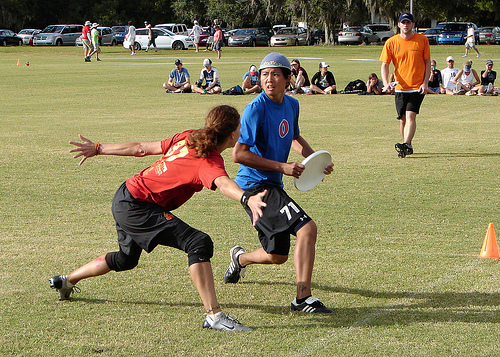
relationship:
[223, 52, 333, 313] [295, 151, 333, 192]
man playing with frisbee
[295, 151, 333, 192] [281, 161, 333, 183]
frisbee in hands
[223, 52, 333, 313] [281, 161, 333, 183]
man has hands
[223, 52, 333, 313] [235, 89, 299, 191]
man wearing a shirt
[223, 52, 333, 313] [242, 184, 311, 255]
man wearing shorts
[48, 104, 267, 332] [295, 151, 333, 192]
woman trying to block frisbee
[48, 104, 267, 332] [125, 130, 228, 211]
woman wearing a shirt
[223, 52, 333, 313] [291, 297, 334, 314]
man wearing shoe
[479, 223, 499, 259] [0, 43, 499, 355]
cone on field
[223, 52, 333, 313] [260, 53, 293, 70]
man wearing hat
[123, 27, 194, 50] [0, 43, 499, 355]
car near field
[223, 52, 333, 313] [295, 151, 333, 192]
man holding frisbee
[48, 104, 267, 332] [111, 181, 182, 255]
woman wearing shorts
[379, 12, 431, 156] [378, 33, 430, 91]
man wearing a shirt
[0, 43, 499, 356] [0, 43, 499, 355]
grass on field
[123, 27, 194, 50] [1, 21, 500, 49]
car in parking lot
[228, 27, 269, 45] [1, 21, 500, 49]
car parked in parking lot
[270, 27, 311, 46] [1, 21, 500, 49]
car parked in parking lot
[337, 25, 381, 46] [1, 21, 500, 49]
car parked in parking lot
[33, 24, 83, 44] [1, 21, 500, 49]
car parked in parking lot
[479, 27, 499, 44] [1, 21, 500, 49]
car parked in parking lot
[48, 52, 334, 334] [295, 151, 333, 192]
people are playing frisbee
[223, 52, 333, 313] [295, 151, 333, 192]
man playing frisbee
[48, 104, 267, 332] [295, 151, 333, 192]
woman playing frisbee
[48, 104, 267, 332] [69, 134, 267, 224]
woman has stretched out hands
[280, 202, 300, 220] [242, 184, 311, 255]
71 on shorts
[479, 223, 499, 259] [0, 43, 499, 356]
cone on grass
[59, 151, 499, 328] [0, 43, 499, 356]
shadows are on grass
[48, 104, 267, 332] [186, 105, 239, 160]
woman has hair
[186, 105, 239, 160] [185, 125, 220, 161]
hair in a ponytail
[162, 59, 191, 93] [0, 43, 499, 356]
person sitting on grass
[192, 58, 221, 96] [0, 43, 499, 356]
person sitting on grass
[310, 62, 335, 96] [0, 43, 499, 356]
person sitting on grass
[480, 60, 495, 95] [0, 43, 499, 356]
person sitting on grass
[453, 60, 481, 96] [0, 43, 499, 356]
person sitting on grass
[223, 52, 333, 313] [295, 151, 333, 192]
man throwing frisbee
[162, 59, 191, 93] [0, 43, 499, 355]
person sitting on field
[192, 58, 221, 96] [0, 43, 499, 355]
person sitting on field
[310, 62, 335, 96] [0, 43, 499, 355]
person sitting on field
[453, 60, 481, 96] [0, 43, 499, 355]
person sitting on field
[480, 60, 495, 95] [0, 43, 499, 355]
person sitting on field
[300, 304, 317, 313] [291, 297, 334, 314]
adidas logo on shoe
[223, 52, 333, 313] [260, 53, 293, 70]
man wearing a hat